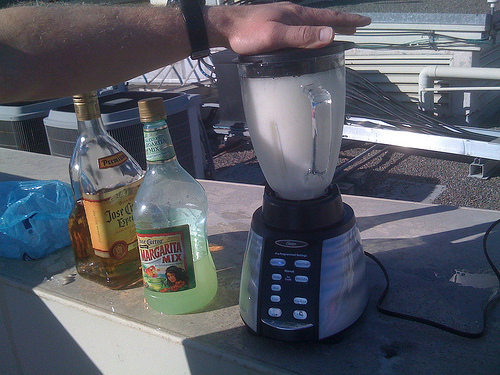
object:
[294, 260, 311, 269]
button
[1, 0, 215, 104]
arm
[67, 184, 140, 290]
beverage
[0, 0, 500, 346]
setup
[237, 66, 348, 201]
beverages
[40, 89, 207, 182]
units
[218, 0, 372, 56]
hand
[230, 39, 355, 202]
blender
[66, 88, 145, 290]
bottle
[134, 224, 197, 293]
label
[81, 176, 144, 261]
label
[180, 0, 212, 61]
band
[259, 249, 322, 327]
buttons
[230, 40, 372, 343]
blenders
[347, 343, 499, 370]
surface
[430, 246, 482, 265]
shadows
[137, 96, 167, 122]
cap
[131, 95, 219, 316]
bottle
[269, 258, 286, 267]
button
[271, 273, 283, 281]
button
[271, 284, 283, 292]
button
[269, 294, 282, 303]
button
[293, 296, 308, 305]
button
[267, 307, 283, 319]
button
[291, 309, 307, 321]
button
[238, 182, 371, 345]
blender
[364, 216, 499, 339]
cord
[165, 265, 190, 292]
woman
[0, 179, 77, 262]
bag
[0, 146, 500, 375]
table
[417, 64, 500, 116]
pipe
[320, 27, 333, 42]
fingernail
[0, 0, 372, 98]
man